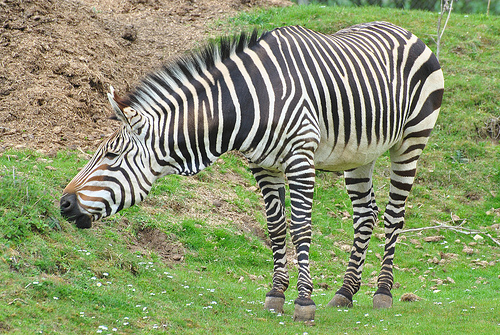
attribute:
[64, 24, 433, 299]
zebra — bending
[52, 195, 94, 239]
nose — black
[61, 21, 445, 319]
zebra — black, white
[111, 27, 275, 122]
mane — striped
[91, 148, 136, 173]
eye — black